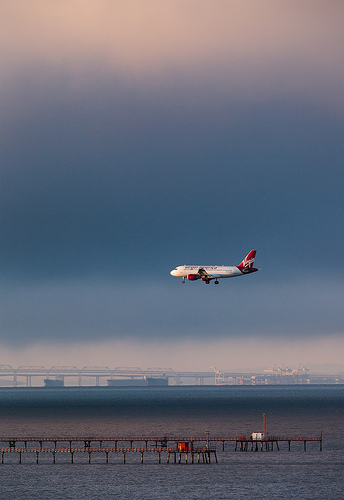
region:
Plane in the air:
[166, 246, 263, 290]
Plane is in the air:
[168, 247, 265, 289]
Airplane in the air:
[168, 247, 264, 284]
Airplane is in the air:
[167, 244, 265, 285]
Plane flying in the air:
[166, 247, 263, 287]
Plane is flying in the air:
[166, 244, 266, 284]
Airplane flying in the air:
[167, 244, 264, 283]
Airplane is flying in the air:
[169, 244, 264, 285]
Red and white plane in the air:
[169, 246, 264, 285]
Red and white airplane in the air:
[168, 247, 264, 286]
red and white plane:
[147, 249, 262, 289]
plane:
[138, 235, 270, 297]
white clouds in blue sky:
[278, 293, 319, 338]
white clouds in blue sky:
[65, 307, 96, 338]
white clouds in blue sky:
[186, 44, 227, 97]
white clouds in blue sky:
[202, 357, 246, 377]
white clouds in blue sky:
[41, 121, 113, 171]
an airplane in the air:
[160, 203, 307, 327]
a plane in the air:
[140, 226, 271, 295]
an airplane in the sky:
[162, 232, 287, 324]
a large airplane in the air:
[170, 246, 263, 295]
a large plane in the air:
[184, 244, 289, 306]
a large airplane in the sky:
[142, 221, 294, 340]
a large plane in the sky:
[151, 234, 315, 314]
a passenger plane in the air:
[150, 226, 309, 327]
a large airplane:
[153, 214, 286, 360]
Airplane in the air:
[168, 248, 259, 284]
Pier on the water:
[0, 412, 324, 464]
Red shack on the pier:
[175, 441, 187, 450]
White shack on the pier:
[251, 431, 266, 439]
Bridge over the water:
[0, 364, 343, 385]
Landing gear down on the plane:
[181, 275, 217, 283]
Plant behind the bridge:
[262, 362, 309, 375]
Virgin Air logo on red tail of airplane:
[236, 249, 258, 273]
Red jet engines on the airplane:
[186, 272, 214, 280]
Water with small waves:
[0, 384, 343, 498]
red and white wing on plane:
[243, 249, 259, 265]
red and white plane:
[168, 248, 263, 285]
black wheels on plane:
[205, 278, 218, 285]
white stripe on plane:
[243, 257, 254, 264]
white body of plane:
[170, 264, 240, 274]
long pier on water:
[1, 434, 325, 446]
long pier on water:
[0, 444, 217, 461]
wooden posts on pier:
[0, 452, 218, 464]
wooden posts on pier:
[6, 440, 320, 448]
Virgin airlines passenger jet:
[159, 244, 273, 289]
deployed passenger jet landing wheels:
[177, 270, 222, 289]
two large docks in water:
[2, 411, 327, 470]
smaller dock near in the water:
[0, 443, 223, 477]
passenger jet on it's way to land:
[166, 249, 273, 292]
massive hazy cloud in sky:
[3, 40, 341, 353]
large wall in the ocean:
[0, 382, 341, 407]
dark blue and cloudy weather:
[0, 0, 343, 360]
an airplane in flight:
[163, 244, 269, 288]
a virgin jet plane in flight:
[162, 239, 267, 289]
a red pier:
[2, 442, 229, 464]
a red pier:
[0, 411, 329, 452]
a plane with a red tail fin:
[166, 244, 265, 289]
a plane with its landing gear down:
[163, 245, 263, 287]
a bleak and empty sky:
[3, 0, 343, 365]